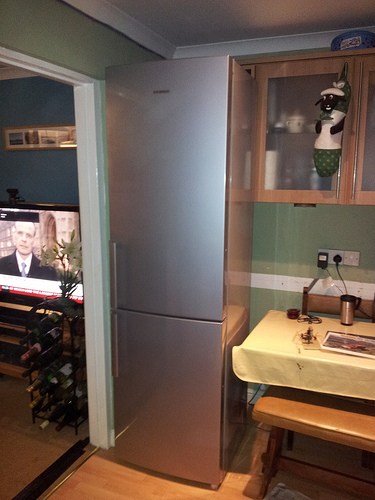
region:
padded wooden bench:
[241, 386, 373, 498]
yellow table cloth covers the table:
[219, 291, 374, 411]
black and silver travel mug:
[333, 287, 360, 334]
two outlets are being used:
[302, 239, 368, 284]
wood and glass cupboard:
[244, 55, 368, 209]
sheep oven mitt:
[300, 50, 354, 190]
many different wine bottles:
[16, 293, 89, 447]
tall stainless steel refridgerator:
[91, 54, 238, 493]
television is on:
[1, 208, 84, 303]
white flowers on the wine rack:
[38, 209, 84, 329]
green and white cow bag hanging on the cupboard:
[314, 64, 352, 177]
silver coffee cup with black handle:
[340, 293, 360, 326]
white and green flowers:
[40, 227, 83, 302]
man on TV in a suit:
[3, 219, 56, 276]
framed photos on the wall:
[2, 125, 77, 148]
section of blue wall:
[0, 77, 81, 201]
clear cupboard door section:
[267, 75, 336, 192]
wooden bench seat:
[253, 386, 373, 492]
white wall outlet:
[317, 247, 359, 266]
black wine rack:
[18, 295, 87, 434]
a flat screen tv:
[1, 191, 80, 294]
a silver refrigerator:
[105, 65, 237, 473]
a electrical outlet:
[301, 244, 360, 269]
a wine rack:
[14, 295, 75, 443]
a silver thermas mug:
[331, 290, 358, 324]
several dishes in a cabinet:
[256, 62, 353, 197]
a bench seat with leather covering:
[247, 400, 367, 461]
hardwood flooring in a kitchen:
[91, 470, 149, 495]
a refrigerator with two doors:
[109, 87, 237, 352]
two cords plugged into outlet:
[307, 243, 360, 283]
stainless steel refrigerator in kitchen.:
[146, 126, 198, 226]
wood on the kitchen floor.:
[87, 474, 135, 493]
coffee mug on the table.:
[342, 296, 356, 323]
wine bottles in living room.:
[31, 339, 65, 409]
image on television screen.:
[18, 228, 64, 250]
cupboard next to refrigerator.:
[281, 88, 308, 173]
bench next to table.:
[271, 407, 366, 458]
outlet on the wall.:
[316, 254, 350, 267]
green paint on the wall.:
[269, 224, 294, 254]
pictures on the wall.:
[4, 129, 70, 149]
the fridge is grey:
[44, 37, 292, 468]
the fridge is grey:
[61, 18, 258, 290]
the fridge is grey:
[128, 76, 308, 313]